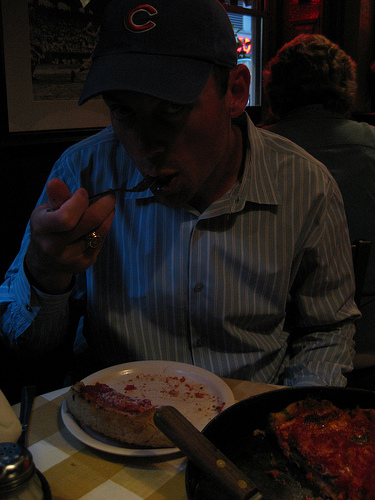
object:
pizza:
[63, 377, 181, 450]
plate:
[59, 358, 237, 458]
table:
[0, 361, 375, 499]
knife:
[150, 403, 334, 499]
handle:
[152, 404, 260, 499]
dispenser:
[0, 439, 39, 498]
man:
[1, 2, 363, 409]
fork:
[47, 172, 167, 213]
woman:
[256, 32, 375, 253]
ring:
[89, 227, 104, 250]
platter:
[186, 384, 375, 498]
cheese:
[14, 479, 48, 498]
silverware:
[16, 383, 41, 451]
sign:
[232, 27, 254, 56]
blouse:
[0, 111, 372, 406]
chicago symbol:
[124, 5, 160, 30]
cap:
[72, 0, 242, 112]